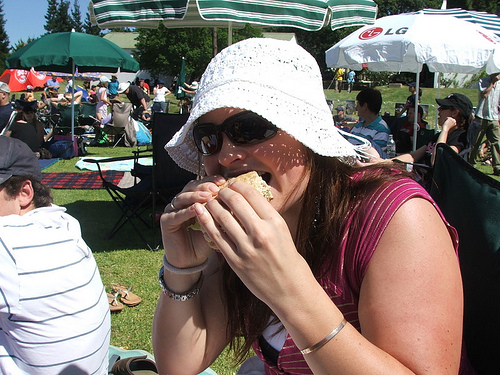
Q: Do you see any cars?
A: No, there are no cars.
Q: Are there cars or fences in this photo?
A: No, there are no cars or fences.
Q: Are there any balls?
A: No, there are no balls.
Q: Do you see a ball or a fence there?
A: No, there are no balls or fences.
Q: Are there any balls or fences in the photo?
A: No, there are no balls or fences.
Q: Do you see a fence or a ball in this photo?
A: No, there are no balls or fences.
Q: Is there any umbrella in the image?
A: Yes, there is an umbrella.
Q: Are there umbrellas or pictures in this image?
A: Yes, there is an umbrella.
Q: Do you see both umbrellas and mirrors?
A: No, there is an umbrella but no mirrors.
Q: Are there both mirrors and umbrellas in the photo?
A: No, there is an umbrella but no mirrors.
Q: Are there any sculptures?
A: No, there are no sculptures.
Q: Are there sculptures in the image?
A: No, there are no sculptures.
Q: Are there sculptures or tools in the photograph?
A: No, there are no sculptures or tools.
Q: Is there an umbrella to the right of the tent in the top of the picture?
A: Yes, there is an umbrella to the right of the tent.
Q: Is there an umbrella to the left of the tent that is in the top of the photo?
A: No, the umbrella is to the right of the tent.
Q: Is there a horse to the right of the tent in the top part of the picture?
A: No, there is an umbrella to the right of the tent.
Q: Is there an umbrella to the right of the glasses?
A: Yes, there is an umbrella to the right of the glasses.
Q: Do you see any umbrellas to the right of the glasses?
A: Yes, there is an umbrella to the right of the glasses.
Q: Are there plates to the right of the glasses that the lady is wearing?
A: No, there is an umbrella to the right of the glasses.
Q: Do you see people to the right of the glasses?
A: Yes, there are people to the right of the glasses.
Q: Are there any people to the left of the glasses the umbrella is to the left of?
A: No, the people are to the right of the glasses.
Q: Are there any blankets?
A: Yes, there is a blanket.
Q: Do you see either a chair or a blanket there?
A: Yes, there is a blanket.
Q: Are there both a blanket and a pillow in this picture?
A: No, there is a blanket but no pillows.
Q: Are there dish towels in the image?
A: No, there are no dish towels.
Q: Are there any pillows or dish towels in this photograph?
A: No, there are no dish towels or pillows.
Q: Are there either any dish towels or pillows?
A: No, there are no dish towels or pillows.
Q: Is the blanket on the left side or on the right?
A: The blanket is on the left of the image.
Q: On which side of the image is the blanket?
A: The blanket is on the left of the image.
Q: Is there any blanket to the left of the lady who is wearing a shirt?
A: Yes, there is a blanket to the left of the lady.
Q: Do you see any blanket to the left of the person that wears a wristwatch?
A: Yes, there is a blanket to the left of the lady.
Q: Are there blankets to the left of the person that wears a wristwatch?
A: Yes, there is a blanket to the left of the lady.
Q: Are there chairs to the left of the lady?
A: No, there is a blanket to the left of the lady.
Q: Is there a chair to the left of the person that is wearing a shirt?
A: No, there is a blanket to the left of the lady.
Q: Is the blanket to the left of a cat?
A: No, the blanket is to the left of a lady.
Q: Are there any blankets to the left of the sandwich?
A: Yes, there is a blanket to the left of the sandwich.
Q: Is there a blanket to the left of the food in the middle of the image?
A: Yes, there is a blanket to the left of the sandwich.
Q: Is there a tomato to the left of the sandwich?
A: No, there is a blanket to the left of the sandwich.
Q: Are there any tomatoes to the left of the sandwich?
A: No, there is a blanket to the left of the sandwich.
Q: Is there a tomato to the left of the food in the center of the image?
A: No, there is a blanket to the left of the sandwich.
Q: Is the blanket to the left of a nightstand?
A: No, the blanket is to the left of a sandwich.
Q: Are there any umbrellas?
A: Yes, there is an umbrella.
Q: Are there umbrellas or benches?
A: Yes, there is an umbrella.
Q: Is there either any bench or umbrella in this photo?
A: Yes, there is an umbrella.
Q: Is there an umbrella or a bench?
A: Yes, there is an umbrella.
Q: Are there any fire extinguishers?
A: No, there are no fire extinguishers.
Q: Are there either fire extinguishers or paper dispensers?
A: No, there are no fire extinguishers or paper dispensers.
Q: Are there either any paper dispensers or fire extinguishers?
A: No, there are no fire extinguishers or paper dispensers.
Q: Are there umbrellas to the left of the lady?
A: Yes, there is an umbrella to the left of the lady.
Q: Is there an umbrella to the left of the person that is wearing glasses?
A: Yes, there is an umbrella to the left of the lady.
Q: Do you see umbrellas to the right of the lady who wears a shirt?
A: No, the umbrella is to the left of the lady.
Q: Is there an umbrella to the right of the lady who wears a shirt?
A: No, the umbrella is to the left of the lady.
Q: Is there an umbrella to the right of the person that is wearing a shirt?
A: No, the umbrella is to the left of the lady.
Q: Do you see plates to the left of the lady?
A: No, there is an umbrella to the left of the lady.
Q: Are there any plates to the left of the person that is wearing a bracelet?
A: No, there is an umbrella to the left of the lady.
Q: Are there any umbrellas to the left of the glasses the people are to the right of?
A: Yes, there is an umbrella to the left of the glasses.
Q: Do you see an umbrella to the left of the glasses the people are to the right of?
A: Yes, there is an umbrella to the left of the glasses.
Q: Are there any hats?
A: Yes, there is a hat.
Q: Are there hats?
A: Yes, there is a hat.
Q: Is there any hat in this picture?
A: Yes, there is a hat.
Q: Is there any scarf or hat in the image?
A: Yes, there is a hat.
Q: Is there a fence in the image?
A: No, there are no fences.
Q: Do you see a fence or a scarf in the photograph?
A: No, there are no fences or scarves.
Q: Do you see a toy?
A: No, there are no toys.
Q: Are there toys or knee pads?
A: No, there are no toys or knee pads.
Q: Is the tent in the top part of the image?
A: Yes, the tent is in the top of the image.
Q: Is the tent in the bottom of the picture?
A: No, the tent is in the top of the image.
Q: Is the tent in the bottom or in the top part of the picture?
A: The tent is in the top of the image.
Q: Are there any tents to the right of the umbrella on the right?
A: No, the tent is to the left of the umbrella.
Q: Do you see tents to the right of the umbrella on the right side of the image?
A: No, the tent is to the left of the umbrella.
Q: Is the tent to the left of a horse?
A: No, the tent is to the left of the umbrella.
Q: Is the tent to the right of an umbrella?
A: No, the tent is to the left of an umbrella.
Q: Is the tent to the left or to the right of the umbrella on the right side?
A: The tent is to the left of the umbrella.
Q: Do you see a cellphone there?
A: No, there are no cell phones.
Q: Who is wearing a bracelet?
A: The lady is wearing a bracelet.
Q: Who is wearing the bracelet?
A: The lady is wearing a bracelet.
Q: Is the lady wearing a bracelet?
A: Yes, the lady is wearing a bracelet.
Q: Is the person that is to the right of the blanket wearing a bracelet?
A: Yes, the lady is wearing a bracelet.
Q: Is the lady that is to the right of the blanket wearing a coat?
A: No, the lady is wearing a bracelet.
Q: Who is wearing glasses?
A: The lady is wearing glasses.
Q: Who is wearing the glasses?
A: The lady is wearing glasses.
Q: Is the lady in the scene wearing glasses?
A: Yes, the lady is wearing glasses.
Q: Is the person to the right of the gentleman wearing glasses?
A: Yes, the lady is wearing glasses.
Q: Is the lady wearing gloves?
A: No, the lady is wearing glasses.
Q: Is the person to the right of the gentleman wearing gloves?
A: No, the lady is wearing glasses.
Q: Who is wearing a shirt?
A: The lady is wearing a shirt.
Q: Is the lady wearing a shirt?
A: Yes, the lady is wearing a shirt.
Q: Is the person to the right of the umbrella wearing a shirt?
A: Yes, the lady is wearing a shirt.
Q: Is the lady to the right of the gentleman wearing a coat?
A: No, the lady is wearing a shirt.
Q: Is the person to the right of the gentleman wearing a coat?
A: No, the lady is wearing a shirt.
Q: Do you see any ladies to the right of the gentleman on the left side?
A: Yes, there is a lady to the right of the gentleman.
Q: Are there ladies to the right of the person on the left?
A: Yes, there is a lady to the right of the gentleman.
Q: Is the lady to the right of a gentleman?
A: Yes, the lady is to the right of a gentleman.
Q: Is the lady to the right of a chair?
A: No, the lady is to the right of a gentleman.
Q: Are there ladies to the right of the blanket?
A: Yes, there is a lady to the right of the blanket.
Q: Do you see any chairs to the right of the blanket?
A: No, there is a lady to the right of the blanket.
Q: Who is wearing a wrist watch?
A: The lady is wearing a wrist watch.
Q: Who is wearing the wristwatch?
A: The lady is wearing a wrist watch.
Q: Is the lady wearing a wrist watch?
A: Yes, the lady is wearing a wrist watch.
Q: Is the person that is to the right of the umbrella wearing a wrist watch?
A: Yes, the lady is wearing a wrist watch.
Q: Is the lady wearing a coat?
A: No, the lady is wearing a wrist watch.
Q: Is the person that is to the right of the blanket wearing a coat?
A: No, the lady is wearing a wrist watch.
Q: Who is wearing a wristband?
A: The lady is wearing a wristband.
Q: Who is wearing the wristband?
A: The lady is wearing a wristband.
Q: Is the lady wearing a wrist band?
A: Yes, the lady is wearing a wrist band.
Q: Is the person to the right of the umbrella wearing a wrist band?
A: Yes, the lady is wearing a wrist band.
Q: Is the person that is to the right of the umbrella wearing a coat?
A: No, the lady is wearing a wrist band.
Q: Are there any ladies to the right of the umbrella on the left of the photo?
A: Yes, there is a lady to the right of the umbrella.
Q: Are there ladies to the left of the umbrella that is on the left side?
A: No, the lady is to the right of the umbrella.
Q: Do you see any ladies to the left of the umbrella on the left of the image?
A: No, the lady is to the right of the umbrella.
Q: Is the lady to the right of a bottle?
A: No, the lady is to the right of the umbrella.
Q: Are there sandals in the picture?
A: Yes, there are sandals.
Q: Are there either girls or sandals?
A: Yes, there are sandals.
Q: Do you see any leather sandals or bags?
A: Yes, there are leather sandals.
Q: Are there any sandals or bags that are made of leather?
A: Yes, the sandals are made of leather.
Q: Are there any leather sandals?
A: Yes, there are sandals that are made of leather.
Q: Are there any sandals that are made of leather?
A: Yes, there are sandals that are made of leather.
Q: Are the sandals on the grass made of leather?
A: Yes, the sandals are made of leather.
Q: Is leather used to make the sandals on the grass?
A: Yes, the sandals are made of leather.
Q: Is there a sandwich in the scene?
A: Yes, there is a sandwich.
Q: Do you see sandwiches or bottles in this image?
A: Yes, there is a sandwich.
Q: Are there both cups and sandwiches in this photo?
A: No, there is a sandwich but no cups.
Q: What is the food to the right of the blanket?
A: The food is a sandwich.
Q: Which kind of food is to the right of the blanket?
A: The food is a sandwich.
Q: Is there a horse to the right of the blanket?
A: No, there is a sandwich to the right of the blanket.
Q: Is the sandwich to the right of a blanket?
A: Yes, the sandwich is to the right of a blanket.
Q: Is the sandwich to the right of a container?
A: No, the sandwich is to the right of a blanket.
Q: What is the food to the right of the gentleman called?
A: The food is a sandwich.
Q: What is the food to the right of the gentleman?
A: The food is a sandwich.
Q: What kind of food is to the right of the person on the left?
A: The food is a sandwich.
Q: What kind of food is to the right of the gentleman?
A: The food is a sandwich.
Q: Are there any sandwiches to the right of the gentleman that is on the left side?
A: Yes, there is a sandwich to the right of the gentleman.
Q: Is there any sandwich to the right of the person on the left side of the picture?
A: Yes, there is a sandwich to the right of the gentleman.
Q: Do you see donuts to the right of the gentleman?
A: No, there is a sandwich to the right of the gentleman.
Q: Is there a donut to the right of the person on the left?
A: No, there is a sandwich to the right of the gentleman.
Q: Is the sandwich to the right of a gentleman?
A: Yes, the sandwich is to the right of a gentleman.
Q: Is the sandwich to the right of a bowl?
A: No, the sandwich is to the right of a gentleman.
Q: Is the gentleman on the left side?
A: Yes, the gentleman is on the left of the image.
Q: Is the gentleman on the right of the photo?
A: No, the gentleman is on the left of the image.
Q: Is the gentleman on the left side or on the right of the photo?
A: The gentleman is on the left of the image.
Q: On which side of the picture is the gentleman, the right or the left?
A: The gentleman is on the left of the image.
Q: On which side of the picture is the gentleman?
A: The gentleman is on the left of the image.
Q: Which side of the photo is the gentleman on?
A: The gentleman is on the left of the image.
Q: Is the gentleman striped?
A: Yes, the gentleman is striped.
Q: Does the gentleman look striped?
A: Yes, the gentleman is striped.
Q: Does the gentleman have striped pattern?
A: Yes, the gentleman is striped.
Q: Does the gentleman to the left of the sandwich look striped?
A: Yes, the gentleman is striped.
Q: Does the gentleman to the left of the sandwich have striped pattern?
A: Yes, the gentleman is striped.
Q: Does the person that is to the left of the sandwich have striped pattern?
A: Yes, the gentleman is striped.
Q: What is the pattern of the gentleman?
A: The gentleman is striped.